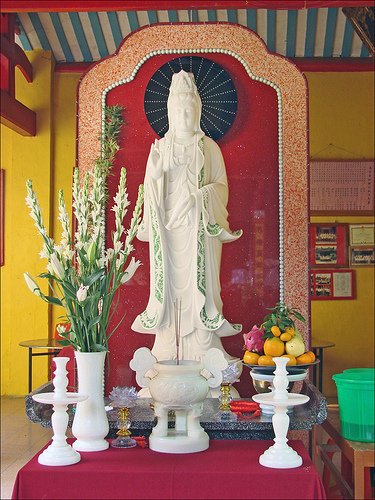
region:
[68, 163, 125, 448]
white vase with white flowers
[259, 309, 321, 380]
s bowl with fruit in it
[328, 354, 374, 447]
a green plastic tub on table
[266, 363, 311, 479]
a white candle holder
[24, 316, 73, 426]
a glass table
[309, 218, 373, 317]
pictures on the wall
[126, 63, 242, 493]
a religious icon on a table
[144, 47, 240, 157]
a round black and white medallion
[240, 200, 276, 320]
reflection on the glass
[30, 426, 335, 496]
red cloth on the altar table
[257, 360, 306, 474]
pedestal on the table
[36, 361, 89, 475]
pedestal on the table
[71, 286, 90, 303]
flower in the vase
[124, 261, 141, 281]
flower in the vase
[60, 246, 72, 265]
flower in the vase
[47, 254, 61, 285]
flower in the vase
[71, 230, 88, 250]
flower in the vase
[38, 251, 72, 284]
flower in the vase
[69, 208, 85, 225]
flower in the vase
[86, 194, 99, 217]
flower in the vase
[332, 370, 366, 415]
a green bucket on a table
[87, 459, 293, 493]
a red table cloth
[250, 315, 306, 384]
a bowl full of fruit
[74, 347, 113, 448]
a white vase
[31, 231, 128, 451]
flowers in a vase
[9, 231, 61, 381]
a yellow wall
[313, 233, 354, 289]
pictures hanging on the wall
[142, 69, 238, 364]
a white statue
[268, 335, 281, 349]
an orange in the bowl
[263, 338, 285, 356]
fruit on the pedestal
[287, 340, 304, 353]
fruit on the pedestal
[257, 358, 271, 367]
fruit on the pedestal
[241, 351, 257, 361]
fruit on the pedestal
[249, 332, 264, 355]
fruit on the pedestal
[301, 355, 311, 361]
fruit on the pedestal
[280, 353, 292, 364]
fruit on the pedestal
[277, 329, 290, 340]
fruit on the pedestal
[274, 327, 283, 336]
fruit on the pedestal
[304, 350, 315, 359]
fruit on the pedestal